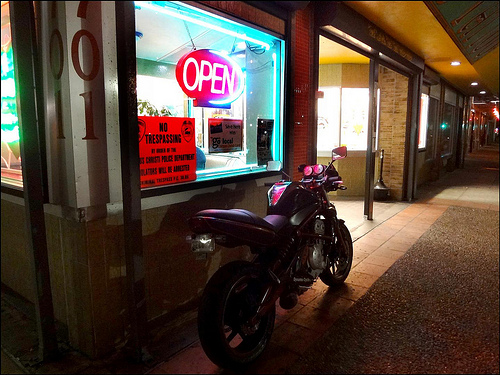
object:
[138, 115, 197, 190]
sign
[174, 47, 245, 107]
sign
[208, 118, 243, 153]
sign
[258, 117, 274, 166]
sign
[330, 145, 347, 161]
side mirror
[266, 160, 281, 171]
side mirror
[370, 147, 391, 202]
ash container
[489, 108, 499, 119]
lights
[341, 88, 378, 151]
window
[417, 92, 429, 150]
lights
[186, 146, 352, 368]
motorcycle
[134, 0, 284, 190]
window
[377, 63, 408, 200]
brick work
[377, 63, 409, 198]
wall